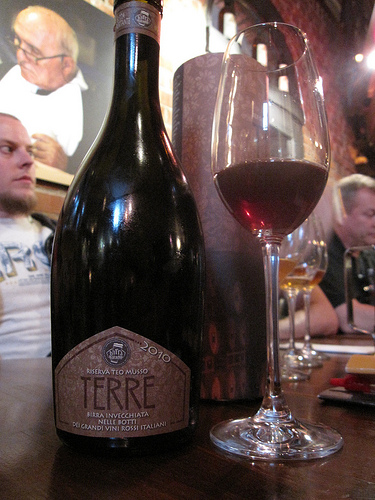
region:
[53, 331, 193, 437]
a label on the bottle of wine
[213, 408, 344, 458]
the base of the wine glass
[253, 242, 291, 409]
the thin handle of the wine glass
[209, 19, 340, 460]
a wine glass with red wine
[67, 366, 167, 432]
Italian writing on the wine bottle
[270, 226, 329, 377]
three more glasses of wine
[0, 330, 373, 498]
a hardwood table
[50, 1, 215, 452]
a bottle of wine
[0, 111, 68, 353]
a man in a white shirt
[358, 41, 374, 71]
a bright light on the ceiling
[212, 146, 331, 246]
dark liquid in the bottom of the glass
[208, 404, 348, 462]
base of the glass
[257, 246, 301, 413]
stem of the glass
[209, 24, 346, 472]
dark wine in a wineglass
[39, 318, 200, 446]
label on the bottom of the bottle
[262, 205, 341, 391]
three wineglasses on the table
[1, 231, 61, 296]
design on the front of the shirt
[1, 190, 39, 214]
hair on the chin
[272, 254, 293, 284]
yellow liquid in the glass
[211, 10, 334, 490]
glass with liquid in it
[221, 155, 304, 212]
liquid in the glass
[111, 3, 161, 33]
label on the neck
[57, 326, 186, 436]
label on the bottle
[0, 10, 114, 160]
screen in the back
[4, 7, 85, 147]
person on the screen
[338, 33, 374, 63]
lights in the room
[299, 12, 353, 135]
brick wall in the back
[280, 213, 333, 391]
glasses on the table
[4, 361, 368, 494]
wooden table with items on it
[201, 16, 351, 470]
A glass of purple wine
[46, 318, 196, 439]
Label on a bottle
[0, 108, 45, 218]
Man has a beard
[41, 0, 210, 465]
A bottle of wine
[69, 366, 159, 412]
"TERRE" written on a label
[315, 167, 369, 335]
Man wearing a black shirt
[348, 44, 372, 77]
A light is turned on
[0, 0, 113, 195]
Painting of a man on the wall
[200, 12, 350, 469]
Glasses are on the table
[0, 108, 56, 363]
Man is wearing a white shirt